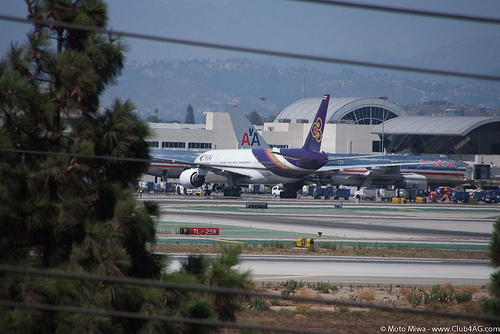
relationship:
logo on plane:
[309, 111, 330, 147] [185, 136, 326, 184]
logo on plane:
[236, 118, 268, 148] [244, 123, 468, 180]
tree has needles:
[10, 3, 139, 288] [105, 33, 121, 56]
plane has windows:
[185, 136, 326, 184] [245, 160, 256, 168]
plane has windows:
[244, 123, 468, 180] [425, 164, 453, 176]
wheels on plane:
[278, 184, 298, 204] [185, 136, 326, 184]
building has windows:
[129, 98, 485, 166] [160, 132, 220, 153]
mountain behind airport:
[145, 57, 295, 100] [147, 111, 472, 146]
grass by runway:
[333, 239, 463, 267] [206, 199, 466, 229]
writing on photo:
[380, 319, 477, 333] [7, 5, 497, 248]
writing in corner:
[380, 319, 477, 333] [365, 279, 498, 331]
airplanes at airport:
[148, 141, 478, 196] [147, 111, 472, 146]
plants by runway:
[409, 284, 477, 313] [206, 199, 466, 229]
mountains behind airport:
[139, 38, 474, 104] [147, 111, 472, 146]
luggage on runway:
[309, 184, 369, 198] [206, 199, 466, 229]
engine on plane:
[177, 163, 212, 192] [185, 136, 326, 184]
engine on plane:
[384, 170, 431, 189] [244, 123, 468, 180]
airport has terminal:
[147, 111, 472, 146] [129, 98, 485, 166]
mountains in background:
[139, 38, 474, 104] [20, 4, 496, 129]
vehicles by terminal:
[357, 186, 408, 199] [147, 111, 472, 146]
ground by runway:
[186, 233, 483, 265] [206, 199, 466, 229]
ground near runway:
[186, 233, 483, 265] [206, 199, 466, 229]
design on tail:
[304, 111, 326, 152] [301, 93, 346, 153]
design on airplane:
[304, 111, 326, 152] [185, 136, 326, 184]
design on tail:
[241, 123, 263, 145] [224, 98, 275, 149]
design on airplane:
[241, 123, 263, 145] [325, 145, 481, 187]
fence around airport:
[26, 260, 194, 328] [147, 111, 472, 146]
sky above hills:
[132, 11, 476, 79] [114, 56, 478, 96]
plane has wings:
[185, 136, 326, 184] [145, 144, 253, 186]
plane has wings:
[244, 123, 468, 180] [341, 161, 431, 187]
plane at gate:
[185, 136, 326, 184] [358, 138, 488, 169]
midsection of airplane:
[333, 150, 374, 172] [325, 145, 481, 187]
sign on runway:
[183, 208, 225, 242] [206, 199, 466, 229]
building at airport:
[129, 98, 485, 166] [147, 111, 472, 146]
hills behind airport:
[114, 56, 478, 96] [147, 111, 472, 146]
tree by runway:
[10, 3, 139, 288] [206, 199, 466, 229]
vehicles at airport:
[357, 186, 408, 199] [147, 111, 472, 146]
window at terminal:
[302, 86, 399, 129] [129, 98, 485, 166]